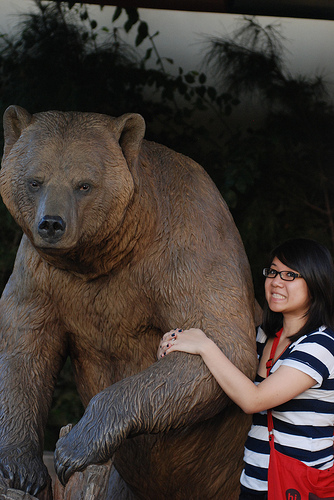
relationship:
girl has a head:
[149, 242, 333, 495] [257, 244, 323, 317]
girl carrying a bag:
[149, 242, 333, 495] [264, 439, 332, 497]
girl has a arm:
[149, 242, 333, 495] [157, 329, 319, 417]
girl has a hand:
[149, 242, 333, 495] [157, 329, 195, 358]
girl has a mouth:
[149, 242, 333, 495] [268, 290, 293, 300]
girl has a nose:
[149, 242, 333, 495] [266, 280, 289, 290]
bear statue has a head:
[7, 99, 265, 386] [3, 104, 149, 260]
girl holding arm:
[149, 242, 333, 495] [44, 342, 260, 480]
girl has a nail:
[149, 242, 333, 495] [170, 328, 188, 333]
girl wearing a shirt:
[149, 242, 333, 495] [235, 329, 333, 499]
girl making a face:
[149, 242, 333, 495] [263, 257, 314, 320]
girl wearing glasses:
[149, 242, 333, 495] [259, 266, 321, 284]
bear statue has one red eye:
[0, 99, 265, 497] [74, 183, 98, 194]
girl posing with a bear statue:
[149, 242, 333, 495] [0, 99, 265, 497]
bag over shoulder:
[264, 439, 332, 497] [285, 326, 333, 377]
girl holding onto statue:
[149, 242, 333, 495] [7, 99, 265, 386]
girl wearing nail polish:
[149, 242, 333, 495] [156, 343, 174, 359]